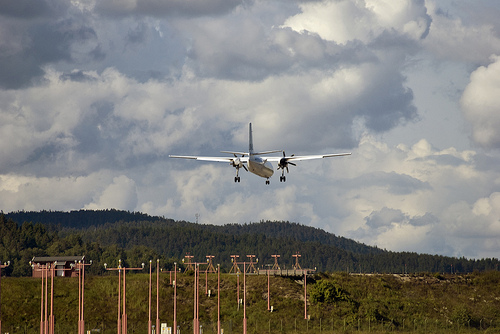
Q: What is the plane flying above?
A: Trees.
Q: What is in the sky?
A: Clouds.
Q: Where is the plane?
A: In the sky.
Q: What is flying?
A: A plane.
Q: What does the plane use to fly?
A: Propellers.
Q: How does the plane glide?
A: Wings.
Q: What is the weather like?
A: Cloudy.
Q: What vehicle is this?
A: Airplane.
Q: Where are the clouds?
A: In the sky.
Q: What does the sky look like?
A: Cloudy.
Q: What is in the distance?
A: Trees.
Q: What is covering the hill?
A: Trees.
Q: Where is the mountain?
A: In the distance.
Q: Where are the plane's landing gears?
A: Bottom of the plane.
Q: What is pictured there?
A: Plane.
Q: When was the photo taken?
A: Daytime.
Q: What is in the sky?
A: Clouds.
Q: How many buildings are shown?
A: One.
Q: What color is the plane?
A: White.